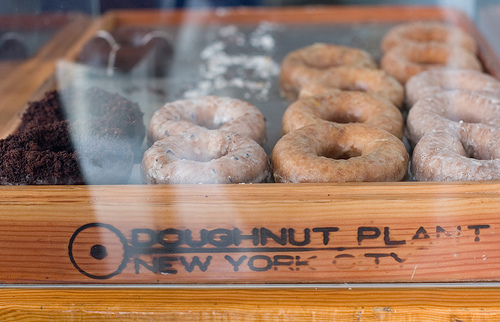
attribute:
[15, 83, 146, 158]
donut — chocolate, round, brown, glazed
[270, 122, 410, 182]
donut — glazed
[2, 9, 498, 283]
tray — brown, square, wooden, wood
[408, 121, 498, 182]
donut — white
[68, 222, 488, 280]
writing — black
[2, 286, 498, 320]
counter — wooden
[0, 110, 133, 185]
donut — dark brown, glazed, chocolate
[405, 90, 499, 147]
donut — glazed, white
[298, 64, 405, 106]
donut — round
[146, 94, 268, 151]
donut — glazed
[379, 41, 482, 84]
donut — round